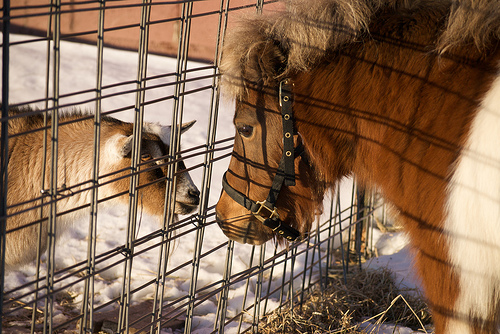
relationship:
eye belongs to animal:
[237, 123, 256, 140] [212, 0, 497, 332]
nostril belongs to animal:
[208, 208, 240, 233] [12, 85, 197, 262]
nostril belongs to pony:
[180, 186, 199, 200] [208, 0, 500, 334]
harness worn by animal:
[218, 32, 300, 238] [212, 0, 497, 332]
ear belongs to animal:
[112, 133, 137, 157] [4, 102, 199, 269]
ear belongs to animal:
[160, 117, 192, 140] [4, 102, 199, 269]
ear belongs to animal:
[240, 21, 295, 83] [212, 0, 497, 332]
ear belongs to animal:
[170, 119, 197, 135] [6, 85, 205, 276]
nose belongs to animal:
[186, 188, 200, 199] [4, 102, 199, 269]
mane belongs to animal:
[246, 1, 483, 51] [212, 0, 497, 332]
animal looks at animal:
[212, 0, 497, 332] [57, 125, 92, 187]